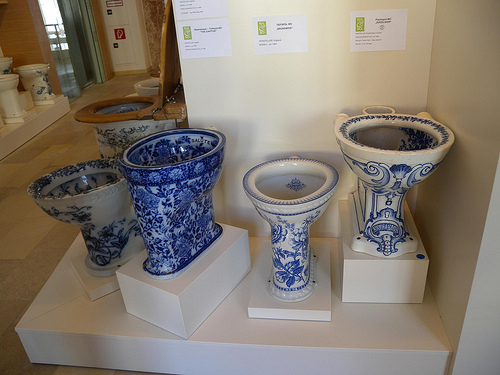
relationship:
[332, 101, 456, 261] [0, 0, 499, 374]
toilet in a showroom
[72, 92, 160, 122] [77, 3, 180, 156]
seat on toilet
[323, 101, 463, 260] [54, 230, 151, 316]
toilet on pedestal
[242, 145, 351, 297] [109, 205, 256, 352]
toilet on pedestal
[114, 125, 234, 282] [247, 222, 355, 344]
toilet on pedestal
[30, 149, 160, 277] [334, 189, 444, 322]
toilet on pedestal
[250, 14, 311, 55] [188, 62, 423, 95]
paper on wall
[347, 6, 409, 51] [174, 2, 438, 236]
paper on wall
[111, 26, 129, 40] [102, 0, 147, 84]
sign on wall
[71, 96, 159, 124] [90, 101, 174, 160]
seat on bowl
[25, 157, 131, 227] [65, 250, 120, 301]
bowl on platform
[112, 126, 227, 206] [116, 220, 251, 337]
bowl on platform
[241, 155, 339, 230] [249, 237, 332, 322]
bowl on platform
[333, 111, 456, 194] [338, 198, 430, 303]
bowl on platform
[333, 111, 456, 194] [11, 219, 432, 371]
bowl on platform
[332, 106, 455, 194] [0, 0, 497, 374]
bowl on showroom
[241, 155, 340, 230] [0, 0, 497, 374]
bowl on showroom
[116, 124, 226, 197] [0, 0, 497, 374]
bowl on showroom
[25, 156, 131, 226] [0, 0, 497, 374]
bowl on showroom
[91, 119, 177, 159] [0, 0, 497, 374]
bowl on showroom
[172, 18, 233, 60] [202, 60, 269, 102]
paper on wall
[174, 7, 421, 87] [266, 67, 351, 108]
signs are on wall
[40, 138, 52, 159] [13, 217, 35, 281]
tile on floor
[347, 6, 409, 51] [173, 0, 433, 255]
paper on wall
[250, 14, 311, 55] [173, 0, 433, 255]
paper on wall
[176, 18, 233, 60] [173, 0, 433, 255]
paper on wall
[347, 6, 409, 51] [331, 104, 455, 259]
paper provide info about bowl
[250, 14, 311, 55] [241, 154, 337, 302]
paper provide info about bowl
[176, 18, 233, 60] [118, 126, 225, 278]
paper provide info about bowl